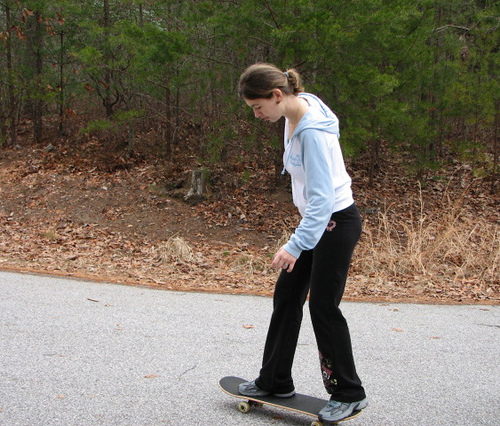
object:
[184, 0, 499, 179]
tree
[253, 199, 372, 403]
pants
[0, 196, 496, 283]
grass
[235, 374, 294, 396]
right shoe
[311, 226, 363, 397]
leg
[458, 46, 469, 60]
nest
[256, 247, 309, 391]
leg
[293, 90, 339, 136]
hood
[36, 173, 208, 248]
dirt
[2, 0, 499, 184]
forest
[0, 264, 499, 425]
street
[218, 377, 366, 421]
paper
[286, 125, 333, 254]
arm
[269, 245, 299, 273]
hand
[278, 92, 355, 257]
jacket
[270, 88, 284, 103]
ear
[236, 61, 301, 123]
head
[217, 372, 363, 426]
skateboard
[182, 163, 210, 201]
stump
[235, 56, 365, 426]
girl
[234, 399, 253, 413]
wheels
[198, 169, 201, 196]
mold